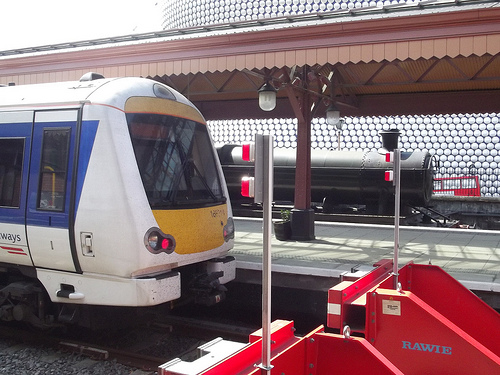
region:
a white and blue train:
[0, 73, 240, 327]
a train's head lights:
[143, 213, 245, 256]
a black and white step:
[23, 261, 108, 310]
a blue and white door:
[24, 100, 99, 275]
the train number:
[196, 197, 236, 222]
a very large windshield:
[113, 97, 238, 220]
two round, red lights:
[233, 138, 268, 200]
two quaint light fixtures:
[236, 74, 350, 124]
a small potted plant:
[274, 205, 294, 243]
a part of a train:
[215, 117, 440, 226]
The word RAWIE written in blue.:
[401, 338, 497, 368]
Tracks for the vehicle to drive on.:
[106, 315, 236, 345]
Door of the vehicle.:
[30, 121, 75, 276]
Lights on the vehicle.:
[140, 225, 180, 265]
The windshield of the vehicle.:
[125, 115, 235, 197]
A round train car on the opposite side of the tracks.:
[229, 145, 441, 200]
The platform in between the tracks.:
[347, 216, 497, 300]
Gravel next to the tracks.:
[23, 348, 94, 373]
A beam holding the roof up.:
[294, 117, 321, 242]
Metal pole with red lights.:
[240, 138, 295, 373]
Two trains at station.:
[0, 57, 435, 294]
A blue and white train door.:
[30, 107, 80, 273]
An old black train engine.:
[231, 111, 444, 223]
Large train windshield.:
[106, 85, 231, 212]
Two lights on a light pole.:
[256, 75, 346, 230]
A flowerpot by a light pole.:
[275, 205, 295, 242]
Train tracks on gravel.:
[112, 315, 232, 360]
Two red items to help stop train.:
[175, 257, 492, 372]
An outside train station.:
[0, 5, 496, 353]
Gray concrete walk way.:
[330, 229, 498, 273]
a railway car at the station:
[1, 72, 246, 339]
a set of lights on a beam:
[256, 74, 356, 134]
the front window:
[116, 92, 236, 224]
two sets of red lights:
[235, 137, 404, 212]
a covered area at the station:
[1, 10, 493, 104]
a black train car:
[206, 132, 434, 222]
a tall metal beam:
[286, 66, 322, 251]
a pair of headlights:
[142, 215, 242, 260]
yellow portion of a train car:
[121, 90, 236, 256]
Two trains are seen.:
[40, 79, 459, 325]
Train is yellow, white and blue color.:
[20, 100, 202, 262]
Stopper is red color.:
[207, 252, 457, 369]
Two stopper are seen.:
[183, 281, 457, 368]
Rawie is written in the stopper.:
[394, 334, 466, 363]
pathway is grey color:
[297, 242, 349, 262]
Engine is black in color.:
[322, 150, 380, 190]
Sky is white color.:
[14, 8, 119, 39]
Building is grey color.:
[168, 5, 215, 15]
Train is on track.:
[28, 260, 263, 353]